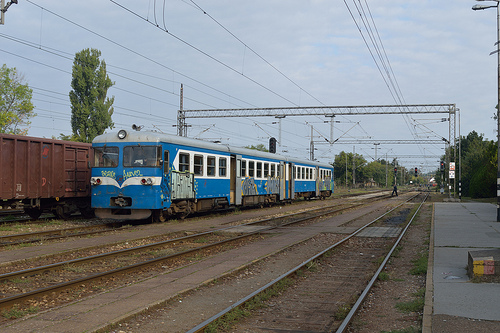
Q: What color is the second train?
A: Blue.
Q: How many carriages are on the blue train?
A: Four.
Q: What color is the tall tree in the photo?
A: Green.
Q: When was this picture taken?
A: Daytime.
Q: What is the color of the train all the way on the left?
A: Brown.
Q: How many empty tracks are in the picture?
A: Two.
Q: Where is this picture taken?
A: A Train Station.